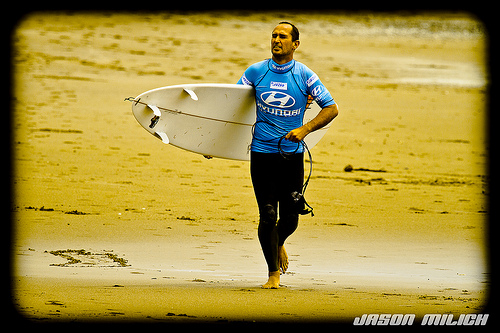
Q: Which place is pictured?
A: It is a beach.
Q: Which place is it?
A: It is a beach.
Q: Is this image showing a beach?
A: Yes, it is showing a beach.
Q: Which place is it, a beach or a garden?
A: It is a beach.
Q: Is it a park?
A: No, it is a beach.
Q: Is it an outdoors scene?
A: Yes, it is outdoors.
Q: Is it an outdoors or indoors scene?
A: It is outdoors.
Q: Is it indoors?
A: No, it is outdoors.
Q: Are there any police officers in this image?
A: No, there are no police officers.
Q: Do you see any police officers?
A: No, there are no police officers.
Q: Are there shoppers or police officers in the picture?
A: No, there are no police officers or shoppers.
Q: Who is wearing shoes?
A: The guy is wearing shoes.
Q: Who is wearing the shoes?
A: The guy is wearing shoes.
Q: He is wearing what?
A: The guy is wearing shoes.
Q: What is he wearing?
A: The guy is wearing shoes.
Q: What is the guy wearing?
A: The guy is wearing shoes.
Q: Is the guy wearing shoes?
A: Yes, the guy is wearing shoes.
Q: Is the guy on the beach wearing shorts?
A: No, the guy is wearing shoes.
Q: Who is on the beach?
A: The guy is on the beach.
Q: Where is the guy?
A: The guy is on the beach.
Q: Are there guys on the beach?
A: Yes, there is a guy on the beach.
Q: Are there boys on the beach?
A: No, there is a guy on the beach.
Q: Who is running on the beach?
A: The guy is running on the beach.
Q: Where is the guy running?
A: The guy is running on the beach.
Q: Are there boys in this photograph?
A: No, there are no boys.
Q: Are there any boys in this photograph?
A: No, there are no boys.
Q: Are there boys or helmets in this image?
A: No, there are no boys or helmets.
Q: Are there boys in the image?
A: No, there are no boys.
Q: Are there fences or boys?
A: No, there are no boys or fences.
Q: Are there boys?
A: No, there are no boys.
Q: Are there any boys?
A: No, there are no boys.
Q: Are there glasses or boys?
A: No, there are no boys or glasses.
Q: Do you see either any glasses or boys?
A: No, there are no boys or glasses.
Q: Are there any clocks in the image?
A: No, there are no clocks.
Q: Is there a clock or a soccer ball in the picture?
A: No, there are no clocks or soccer balls.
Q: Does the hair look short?
A: Yes, the hair is short.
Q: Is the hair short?
A: Yes, the hair is short.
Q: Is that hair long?
A: No, the hair is short.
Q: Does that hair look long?
A: No, the hair is short.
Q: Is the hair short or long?
A: The hair is short.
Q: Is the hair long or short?
A: The hair is short.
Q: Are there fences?
A: No, there are no fences.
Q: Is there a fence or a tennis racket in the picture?
A: No, there are no fences or rackets.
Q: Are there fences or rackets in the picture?
A: No, there are no fences or rackets.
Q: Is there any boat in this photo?
A: No, there are no boats.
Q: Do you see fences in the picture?
A: No, there are no fences.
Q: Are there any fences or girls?
A: No, there are no fences or girls.